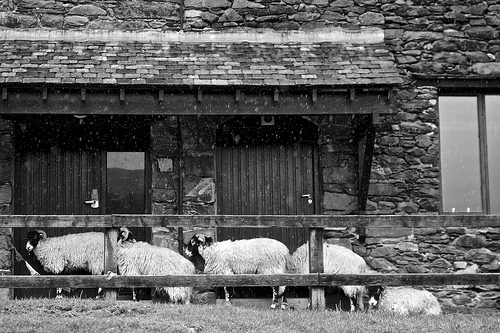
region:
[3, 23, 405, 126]
Awning on side of building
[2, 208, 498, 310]
Wooden fence on grass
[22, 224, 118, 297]
White and black sheep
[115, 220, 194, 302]
White and black sheep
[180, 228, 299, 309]
White and black sheep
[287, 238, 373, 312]
Sheep standing on grass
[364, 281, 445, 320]
Black and white sheep laying down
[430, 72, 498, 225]
Window on side of building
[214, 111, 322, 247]
Wooden door on building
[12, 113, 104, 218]
Wooden door on building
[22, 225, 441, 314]
the sheep on the grass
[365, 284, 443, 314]
the sheep lying down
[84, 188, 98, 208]
the handle on the door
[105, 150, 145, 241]
the window on the building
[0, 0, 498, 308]
the building behind the sheep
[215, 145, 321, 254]
the door on the building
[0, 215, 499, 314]
the fence near the sheep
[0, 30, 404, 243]
the porch roof on the building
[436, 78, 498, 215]
the window on the building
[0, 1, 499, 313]
the rocks that make up the building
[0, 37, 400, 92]
the shingles on the roof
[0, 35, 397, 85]
the roof over the doorway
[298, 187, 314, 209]
the lock on the door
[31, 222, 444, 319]
the sheep in the fenced area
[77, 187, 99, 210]
the handle for the front door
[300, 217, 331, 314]
the post for the fence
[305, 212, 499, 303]
the wooden fence in front of the house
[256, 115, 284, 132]
the object over the door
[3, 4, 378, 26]
the stone wall above the canopy roofe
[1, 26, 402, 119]
Awning attached to building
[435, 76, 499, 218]
Window attached to building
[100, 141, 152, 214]
Small window next to door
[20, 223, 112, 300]
Black and white sheep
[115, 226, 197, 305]
Black and white sheep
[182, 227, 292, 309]
Black and white sheep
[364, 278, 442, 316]
Sheep laying down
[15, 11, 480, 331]
an old photo of a farm scene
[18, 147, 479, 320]
these sheep are in a farm area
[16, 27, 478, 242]
they are standing by a building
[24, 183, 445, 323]
there are five sheep in the picture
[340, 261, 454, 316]
this sheep is lying on the ground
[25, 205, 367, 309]
these four sheep are standing up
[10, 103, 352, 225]
two doors to a building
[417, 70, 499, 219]
a window in the building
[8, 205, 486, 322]
a wooden fence to contain the sheep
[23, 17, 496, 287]
this building is made out of stone and brick